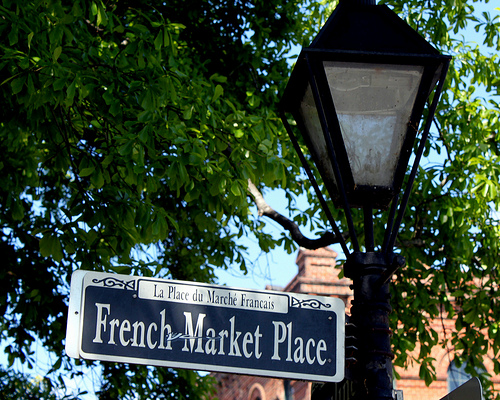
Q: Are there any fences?
A: No, there are no fences.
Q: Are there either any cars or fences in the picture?
A: No, there are no fences or cars.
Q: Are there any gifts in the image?
A: No, there are no gifts.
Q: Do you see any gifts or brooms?
A: No, there are no gifts or brooms.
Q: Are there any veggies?
A: No, there are no veggies.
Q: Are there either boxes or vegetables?
A: No, there are no vegetables or boxes.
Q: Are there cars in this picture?
A: No, there are no cars.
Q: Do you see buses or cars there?
A: No, there are no cars or buses.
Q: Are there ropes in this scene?
A: No, there are no ropes.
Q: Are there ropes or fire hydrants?
A: No, there are no ropes or fire hydrants.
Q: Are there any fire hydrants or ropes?
A: No, there are no ropes or fire hydrants.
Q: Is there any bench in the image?
A: No, there are no benches.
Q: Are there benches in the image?
A: No, there are no benches.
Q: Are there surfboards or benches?
A: No, there are no benches or surfboards.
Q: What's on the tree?
A: The leaves are on the tree.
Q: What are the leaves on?
A: The leaves are on the tree.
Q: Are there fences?
A: No, there are no fences.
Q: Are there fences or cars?
A: No, there are no fences or cars.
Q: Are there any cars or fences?
A: No, there are no fences or cars.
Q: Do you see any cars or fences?
A: No, there are no fences or cars.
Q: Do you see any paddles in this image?
A: No, there are no paddles.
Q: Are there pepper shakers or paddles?
A: No, there are no paddles or pepper shakers.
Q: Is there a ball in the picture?
A: No, there are no balls.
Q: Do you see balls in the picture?
A: No, there are no balls.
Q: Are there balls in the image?
A: No, there are no balls.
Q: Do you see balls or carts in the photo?
A: No, there are no balls or carts.